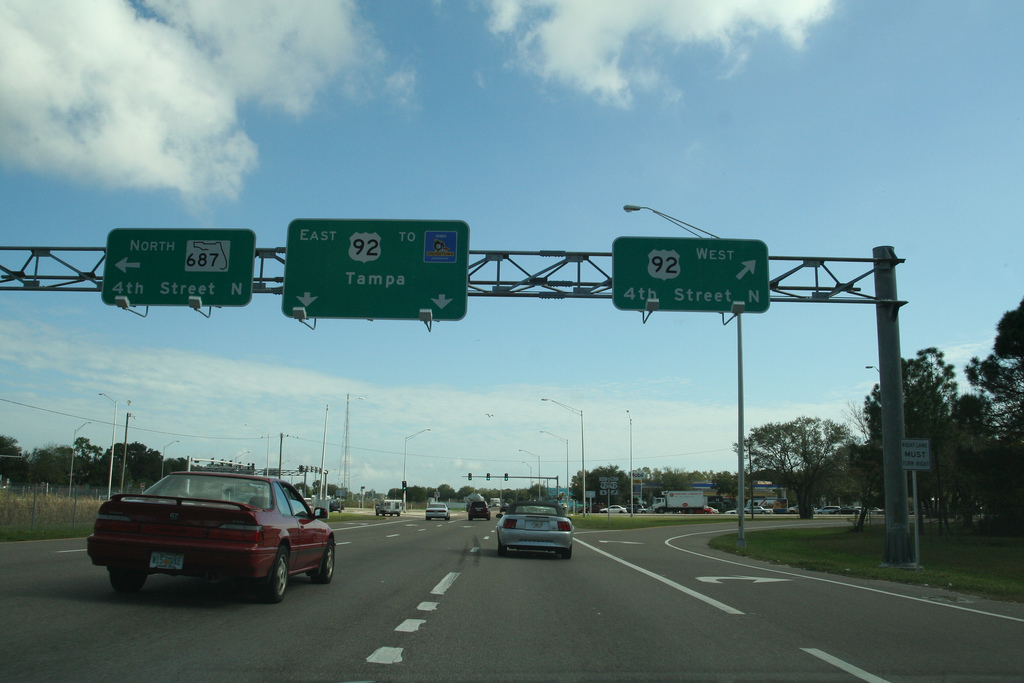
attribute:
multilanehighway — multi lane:
[21, 480, 1020, 680]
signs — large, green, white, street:
[83, 216, 789, 328]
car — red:
[99, 458, 333, 605]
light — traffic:
[463, 471, 473, 482]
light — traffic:
[479, 465, 493, 482]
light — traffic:
[498, 468, 515, 482]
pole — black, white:
[902, 467, 929, 556]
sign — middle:
[286, 218, 470, 320]